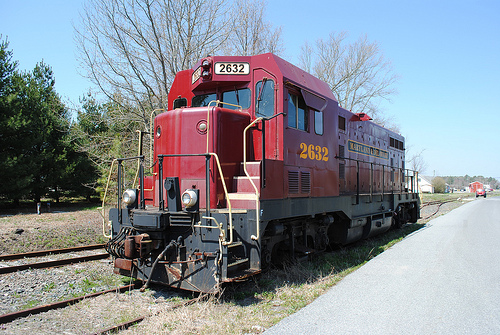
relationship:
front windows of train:
[177, 72, 292, 126] [70, 52, 440, 292]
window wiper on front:
[246, 74, 272, 107] [100, 57, 283, 309]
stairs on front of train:
[217, 159, 260, 215] [120, 68, 421, 286]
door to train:
[252, 67, 277, 157] [102, 56, 417, 299]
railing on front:
[157, 151, 214, 230] [100, 57, 283, 309]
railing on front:
[116, 153, 146, 218] [100, 57, 283, 309]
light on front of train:
[177, 191, 196, 207] [100, 33, 422, 291]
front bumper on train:
[66, 198, 247, 306] [70, 52, 440, 292]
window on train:
[286, 85, 306, 132] [102, 56, 417, 299]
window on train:
[314, 109, 327, 136] [102, 56, 417, 299]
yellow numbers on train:
[287, 131, 359, 176] [102, 56, 417, 299]